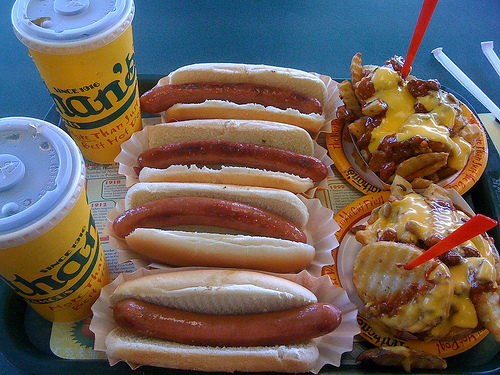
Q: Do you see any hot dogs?
A: Yes, there is a hot dog.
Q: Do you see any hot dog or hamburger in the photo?
A: Yes, there is a hot dog.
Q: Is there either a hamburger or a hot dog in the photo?
A: Yes, there is a hot dog.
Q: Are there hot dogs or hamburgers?
A: Yes, there is a hot dog.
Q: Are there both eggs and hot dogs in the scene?
A: No, there is a hot dog but no eggs.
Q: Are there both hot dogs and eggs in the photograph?
A: No, there is a hot dog but no eggs.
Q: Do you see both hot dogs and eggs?
A: No, there is a hot dog but no eggs.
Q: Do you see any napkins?
A: No, there are no napkins.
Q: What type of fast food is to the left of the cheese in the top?
A: The food is a hot dog.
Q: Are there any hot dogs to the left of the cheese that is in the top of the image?
A: Yes, there is a hot dog to the left of the cheese.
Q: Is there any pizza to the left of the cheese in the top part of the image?
A: No, there is a hot dog to the left of the cheese.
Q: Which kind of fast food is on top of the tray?
A: The food is a hot dog.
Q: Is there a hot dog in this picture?
A: Yes, there is a hot dog.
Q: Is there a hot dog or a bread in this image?
A: Yes, there is a hot dog.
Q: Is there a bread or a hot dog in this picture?
A: Yes, there is a hot dog.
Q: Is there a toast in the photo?
A: No, there are no toasts.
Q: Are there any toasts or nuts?
A: No, there are no toasts or nuts.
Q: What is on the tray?
A: The hot dog is on the tray.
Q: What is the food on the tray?
A: The food is a hot dog.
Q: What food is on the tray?
A: The food is a hot dog.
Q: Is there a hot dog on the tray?
A: Yes, there is a hot dog on the tray.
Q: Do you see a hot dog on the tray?
A: Yes, there is a hot dog on the tray.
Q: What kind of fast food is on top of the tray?
A: The food is a hot dog.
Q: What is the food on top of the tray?
A: The food is a hot dog.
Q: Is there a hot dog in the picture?
A: Yes, there is a hot dog.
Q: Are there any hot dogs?
A: Yes, there is a hot dog.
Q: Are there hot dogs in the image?
A: Yes, there is a hot dog.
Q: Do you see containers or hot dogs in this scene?
A: Yes, there is a hot dog.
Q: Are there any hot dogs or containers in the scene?
A: Yes, there is a hot dog.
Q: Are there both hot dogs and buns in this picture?
A: Yes, there are both a hot dog and a bun.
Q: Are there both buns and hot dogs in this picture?
A: Yes, there are both a hot dog and a bun.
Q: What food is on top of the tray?
A: The food is a hot dog.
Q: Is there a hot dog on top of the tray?
A: Yes, there is a hot dog on top of the tray.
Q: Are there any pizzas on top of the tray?
A: No, there is a hot dog on top of the tray.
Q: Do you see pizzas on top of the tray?
A: No, there is a hot dog on top of the tray.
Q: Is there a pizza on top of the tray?
A: No, there is a hot dog on top of the tray.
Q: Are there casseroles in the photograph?
A: No, there are no casseroles.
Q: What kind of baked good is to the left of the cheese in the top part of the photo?
A: The food is buns.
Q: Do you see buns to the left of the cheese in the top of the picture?
A: Yes, there are buns to the left of the cheese.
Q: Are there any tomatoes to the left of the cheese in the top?
A: No, there are buns to the left of the cheese.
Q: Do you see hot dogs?
A: Yes, there is a hot dog.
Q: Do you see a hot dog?
A: Yes, there is a hot dog.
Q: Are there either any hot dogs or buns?
A: Yes, there is a hot dog.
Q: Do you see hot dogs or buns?
A: Yes, there is a hot dog.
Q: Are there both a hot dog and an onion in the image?
A: No, there is a hot dog but no onions.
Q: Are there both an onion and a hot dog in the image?
A: No, there is a hot dog but no onions.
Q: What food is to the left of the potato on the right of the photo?
A: The food is a hot dog.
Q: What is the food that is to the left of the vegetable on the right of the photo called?
A: The food is a hot dog.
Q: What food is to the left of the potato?
A: The food is a hot dog.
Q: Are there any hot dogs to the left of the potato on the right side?
A: Yes, there is a hot dog to the left of the potato.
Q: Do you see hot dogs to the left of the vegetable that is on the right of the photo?
A: Yes, there is a hot dog to the left of the potato.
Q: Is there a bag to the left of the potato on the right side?
A: No, there is a hot dog to the left of the potato.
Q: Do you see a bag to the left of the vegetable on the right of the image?
A: No, there is a hot dog to the left of the potato.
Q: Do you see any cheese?
A: Yes, there is cheese.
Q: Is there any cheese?
A: Yes, there is cheese.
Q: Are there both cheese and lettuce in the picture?
A: No, there is cheese but no lettuce.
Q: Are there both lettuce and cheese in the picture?
A: No, there is cheese but no lettuce.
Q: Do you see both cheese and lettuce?
A: No, there is cheese but no lettuce.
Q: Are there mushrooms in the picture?
A: No, there are no mushrooms.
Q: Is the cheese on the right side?
A: Yes, the cheese is on the right of the image.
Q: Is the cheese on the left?
A: No, the cheese is on the right of the image.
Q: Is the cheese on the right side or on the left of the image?
A: The cheese is on the right of the image.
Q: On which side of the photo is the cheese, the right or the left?
A: The cheese is on the right of the image.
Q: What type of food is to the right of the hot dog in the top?
A: The food is cheese.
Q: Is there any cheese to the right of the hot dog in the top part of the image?
A: Yes, there is cheese to the right of the hot dog.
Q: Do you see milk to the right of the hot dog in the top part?
A: No, there is cheese to the right of the hot dog.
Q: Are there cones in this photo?
A: No, there are no cones.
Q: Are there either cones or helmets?
A: No, there are no cones or helmets.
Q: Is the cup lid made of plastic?
A: Yes, the lid is made of plastic.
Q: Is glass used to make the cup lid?
A: No, the lid is made of plastic.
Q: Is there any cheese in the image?
A: Yes, there is cheese.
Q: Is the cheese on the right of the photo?
A: Yes, the cheese is on the right of the image.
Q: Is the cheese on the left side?
A: No, the cheese is on the right of the image.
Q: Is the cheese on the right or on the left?
A: The cheese is on the right of the image.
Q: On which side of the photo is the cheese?
A: The cheese is on the right of the image.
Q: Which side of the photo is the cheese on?
A: The cheese is on the right of the image.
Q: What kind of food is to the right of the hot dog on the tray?
A: The food is cheese.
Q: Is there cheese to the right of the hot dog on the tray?
A: Yes, there is cheese to the right of the hot dog.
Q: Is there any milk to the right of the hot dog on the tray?
A: No, there is cheese to the right of the hot dog.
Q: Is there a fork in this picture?
A: Yes, there is a fork.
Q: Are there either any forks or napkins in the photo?
A: Yes, there is a fork.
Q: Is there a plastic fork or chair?
A: Yes, there is a plastic fork.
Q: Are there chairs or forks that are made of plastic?
A: Yes, the fork is made of plastic.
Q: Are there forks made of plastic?
A: Yes, there is a fork that is made of plastic.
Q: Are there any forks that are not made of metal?
A: Yes, there is a fork that is made of plastic.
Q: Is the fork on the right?
A: Yes, the fork is on the right of the image.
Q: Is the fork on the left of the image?
A: No, the fork is on the right of the image.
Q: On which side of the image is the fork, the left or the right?
A: The fork is on the right of the image.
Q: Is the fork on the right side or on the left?
A: The fork is on the right of the image.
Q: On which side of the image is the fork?
A: The fork is on the right of the image.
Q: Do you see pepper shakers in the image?
A: No, there are no pepper shakers.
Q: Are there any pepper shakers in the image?
A: No, there are no pepper shakers.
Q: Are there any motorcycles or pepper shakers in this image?
A: No, there are no pepper shakers or motorcycles.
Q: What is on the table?
A: The tray is on the table.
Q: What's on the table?
A: The tray is on the table.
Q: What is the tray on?
A: The tray is on the table.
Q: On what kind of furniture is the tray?
A: The tray is on the table.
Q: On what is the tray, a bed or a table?
A: The tray is on a table.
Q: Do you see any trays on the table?
A: Yes, there is a tray on the table.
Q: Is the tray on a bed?
A: No, the tray is on the table.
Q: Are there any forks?
A: Yes, there is a fork.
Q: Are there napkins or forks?
A: Yes, there is a fork.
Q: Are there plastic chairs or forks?
A: Yes, there is a plastic fork.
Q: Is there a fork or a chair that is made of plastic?
A: Yes, the fork is made of plastic.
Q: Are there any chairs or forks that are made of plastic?
A: Yes, the fork is made of plastic.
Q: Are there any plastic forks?
A: Yes, there is a fork that is made of plastic.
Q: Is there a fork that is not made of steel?
A: Yes, there is a fork that is made of plastic.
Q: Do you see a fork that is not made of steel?
A: Yes, there is a fork that is made of plastic.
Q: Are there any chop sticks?
A: No, there are no chop sticks.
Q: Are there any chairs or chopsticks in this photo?
A: No, there are no chopsticks or chairs.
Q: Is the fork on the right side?
A: Yes, the fork is on the right of the image.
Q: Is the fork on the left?
A: No, the fork is on the right of the image.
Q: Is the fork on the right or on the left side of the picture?
A: The fork is on the right of the image.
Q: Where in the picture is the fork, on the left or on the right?
A: The fork is on the right of the image.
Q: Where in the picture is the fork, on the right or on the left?
A: The fork is on the right of the image.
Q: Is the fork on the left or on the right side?
A: The fork is on the right of the image.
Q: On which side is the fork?
A: The fork is on the right of the image.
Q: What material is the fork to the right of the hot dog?
A: The fork is made of plastic.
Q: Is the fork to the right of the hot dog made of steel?
A: No, the fork is made of plastic.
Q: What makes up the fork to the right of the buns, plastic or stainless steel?
A: The fork is made of plastic.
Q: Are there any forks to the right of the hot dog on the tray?
A: Yes, there is a fork to the right of the hot dog.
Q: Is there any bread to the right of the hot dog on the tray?
A: No, there is a fork to the right of the hot dog.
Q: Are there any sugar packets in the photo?
A: No, there are no sugar packets.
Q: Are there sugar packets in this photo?
A: No, there are no sugar packets.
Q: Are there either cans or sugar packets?
A: No, there are no sugar packets or cans.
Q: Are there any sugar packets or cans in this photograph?
A: No, there are no sugar packets or cans.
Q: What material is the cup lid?
A: The lid is made of plastic.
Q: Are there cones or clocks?
A: No, there are no cones or clocks.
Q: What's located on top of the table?
A: The straw is on top of the table.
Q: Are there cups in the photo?
A: Yes, there is a cup.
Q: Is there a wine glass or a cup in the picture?
A: Yes, there is a cup.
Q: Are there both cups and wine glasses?
A: No, there is a cup but no wine glasses.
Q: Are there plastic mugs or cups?
A: Yes, there is a plastic cup.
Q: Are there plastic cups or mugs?
A: Yes, there is a plastic cup.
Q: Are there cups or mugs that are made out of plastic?
A: Yes, the cup is made of plastic.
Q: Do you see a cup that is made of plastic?
A: Yes, there is a cup that is made of plastic.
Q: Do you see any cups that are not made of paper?
A: Yes, there is a cup that is made of plastic.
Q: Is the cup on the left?
A: Yes, the cup is on the left of the image.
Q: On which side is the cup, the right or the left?
A: The cup is on the left of the image.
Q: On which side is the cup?
A: The cup is on the left of the image.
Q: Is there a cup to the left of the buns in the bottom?
A: Yes, there is a cup to the left of the buns.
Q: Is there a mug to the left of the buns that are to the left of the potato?
A: No, there is a cup to the left of the buns.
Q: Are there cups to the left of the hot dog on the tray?
A: Yes, there is a cup to the left of the hot dog.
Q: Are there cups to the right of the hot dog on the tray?
A: No, the cup is to the left of the hot dog.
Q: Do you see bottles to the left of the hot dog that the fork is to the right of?
A: No, there is a cup to the left of the hot dog.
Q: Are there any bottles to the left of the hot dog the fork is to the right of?
A: No, there is a cup to the left of the hot dog.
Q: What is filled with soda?
A: The cup is filled with soda.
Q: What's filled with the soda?
A: The cup is filled with soda.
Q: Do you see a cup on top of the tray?
A: Yes, there is a cup on top of the tray.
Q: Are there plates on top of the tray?
A: No, there is a cup on top of the tray.